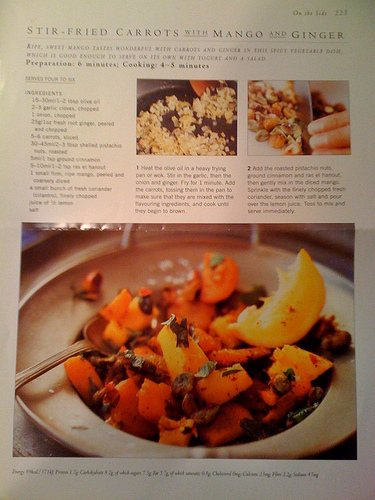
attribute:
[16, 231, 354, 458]
plate — round, large, wide, yellow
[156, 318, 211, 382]
food —  colorful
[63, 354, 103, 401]
food — orange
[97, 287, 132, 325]
food — orange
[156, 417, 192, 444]
food — small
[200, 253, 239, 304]
food — orange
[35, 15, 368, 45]
title — black, long, thin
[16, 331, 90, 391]
utensil — round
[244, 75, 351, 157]
image — small, yellow, brown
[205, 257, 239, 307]
carrot —  orange, blurry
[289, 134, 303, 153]
ground — clustered, orange, brown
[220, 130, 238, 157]
ground — yellow, chopped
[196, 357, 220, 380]
herb — green, small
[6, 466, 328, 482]
caption — small, long, black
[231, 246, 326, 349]
lemon wedge — wedged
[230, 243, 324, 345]
slice — lemon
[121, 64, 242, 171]
picture — photocopied, blurry, colorful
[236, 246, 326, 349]
lemon — yellow, sliced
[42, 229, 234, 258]
plate — round, white, wide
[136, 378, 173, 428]
food — colorful, yellow, orange, green, brown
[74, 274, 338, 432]
food — yellow, orange, grouped, brown, green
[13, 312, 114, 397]
spoon — silver, small, metal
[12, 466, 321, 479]
information — tiny, writing, nutrional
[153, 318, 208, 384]
peice — yellow, brown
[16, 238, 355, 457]
bowl — round, white, wide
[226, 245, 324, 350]
wedge — yellow, large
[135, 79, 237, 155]
bread crumbs — ground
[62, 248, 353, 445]
ingredients — cut, mixed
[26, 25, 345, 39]
name — dish, capitalized, underlined